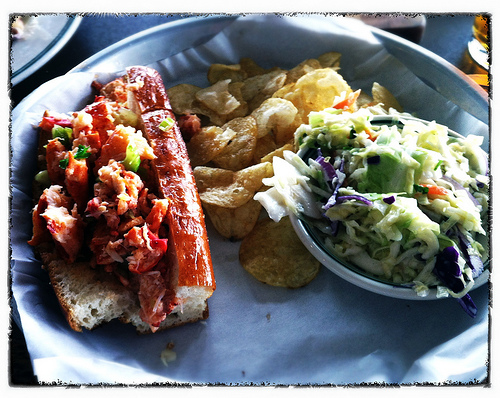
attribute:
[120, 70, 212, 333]
bread — toasted, red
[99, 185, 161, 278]
meat — beef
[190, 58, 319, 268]
potato chips — crispy, piled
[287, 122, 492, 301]
bowl — small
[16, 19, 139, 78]
border — blue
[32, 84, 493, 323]
meal — tasty, good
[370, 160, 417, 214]
lettuce — piece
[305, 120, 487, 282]
salad — healthy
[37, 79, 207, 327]
sandwich — big, meaty, crispy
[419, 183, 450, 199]
carrot — small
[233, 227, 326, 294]
potato chip — single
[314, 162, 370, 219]
cabbage — purple, red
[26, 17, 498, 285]
table — blue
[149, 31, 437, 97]
liner — paper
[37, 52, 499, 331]
food — colorful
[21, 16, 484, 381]
plate — white